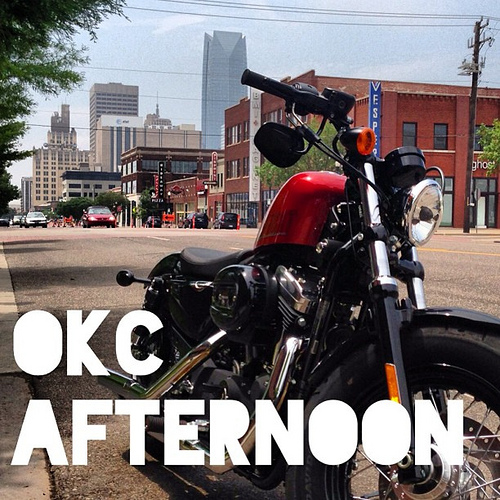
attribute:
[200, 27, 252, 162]
building — side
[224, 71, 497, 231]
building — brick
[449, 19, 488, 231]
pole — wooden, electric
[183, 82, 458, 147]
building — brick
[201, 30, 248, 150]
building — tall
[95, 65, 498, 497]
motorcycle — parked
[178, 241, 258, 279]
black seat — leather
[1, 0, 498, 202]
sky — overcast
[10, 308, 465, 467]
letters — white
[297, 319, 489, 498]
wheel — black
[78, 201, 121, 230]
car — red, sedan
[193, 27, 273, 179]
building — tall, glass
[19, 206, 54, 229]
car — gray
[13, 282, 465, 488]
word phrase — short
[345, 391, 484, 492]
spokes — chrome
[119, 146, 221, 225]
building — brick